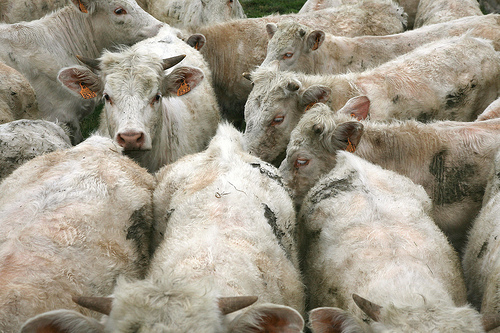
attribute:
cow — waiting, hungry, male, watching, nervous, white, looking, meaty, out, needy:
[54, 23, 223, 174]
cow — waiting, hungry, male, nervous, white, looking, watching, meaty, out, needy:
[240, 28, 500, 168]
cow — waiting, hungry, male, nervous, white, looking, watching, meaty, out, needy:
[279, 94, 498, 248]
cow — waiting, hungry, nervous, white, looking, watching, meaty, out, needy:
[251, 13, 498, 78]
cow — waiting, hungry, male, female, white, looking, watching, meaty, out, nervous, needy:
[177, 1, 413, 128]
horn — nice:
[71, 50, 102, 73]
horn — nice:
[158, 54, 184, 79]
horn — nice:
[313, 123, 325, 136]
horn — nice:
[286, 80, 300, 94]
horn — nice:
[240, 70, 252, 82]